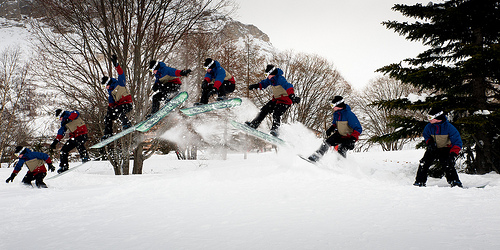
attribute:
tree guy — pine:
[382, 4, 498, 187]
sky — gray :
[252, 8, 412, 68]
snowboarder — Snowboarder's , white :
[305, 79, 497, 221]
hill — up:
[1, 93, 481, 249]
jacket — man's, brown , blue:
[414, 124, 465, 158]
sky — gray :
[15, 4, 493, 161]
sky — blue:
[0, 2, 458, 140]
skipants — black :
[310, 130, 352, 161]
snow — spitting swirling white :
[6, 97, 499, 248]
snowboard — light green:
[94, 95, 211, 152]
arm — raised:
[103, 40, 134, 90]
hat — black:
[395, 102, 482, 229]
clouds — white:
[262, 8, 314, 56]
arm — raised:
[237, 78, 283, 105]